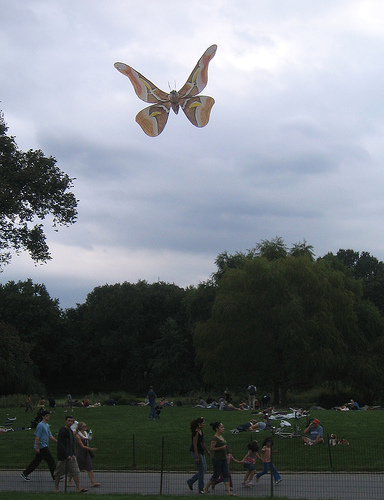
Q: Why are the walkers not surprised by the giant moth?
A: It is a kite.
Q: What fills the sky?
A: Clouds.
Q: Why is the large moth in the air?
A: It's flying.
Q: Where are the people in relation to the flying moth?
A: Below the moth.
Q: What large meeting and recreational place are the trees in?
A: Park.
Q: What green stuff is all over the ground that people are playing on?
A: Grass.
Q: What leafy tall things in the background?
A: Trees.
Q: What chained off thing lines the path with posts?
A: Fence.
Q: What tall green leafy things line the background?
A: Trees.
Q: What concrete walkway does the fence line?
A: Sidewalk.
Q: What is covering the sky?
A: Clouds.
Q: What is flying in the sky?
A: Butterfly Kite.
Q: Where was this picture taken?
A: At a park.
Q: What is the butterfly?
A: A kite.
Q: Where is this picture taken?
A: A park.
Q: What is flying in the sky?
A: A kite.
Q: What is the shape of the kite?
A: A butterfly.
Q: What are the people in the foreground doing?
A: Walking.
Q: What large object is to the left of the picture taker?
A: A tree.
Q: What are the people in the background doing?
A: Laying on the grass.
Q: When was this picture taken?
A: During daylight.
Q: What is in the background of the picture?
A: Trees.